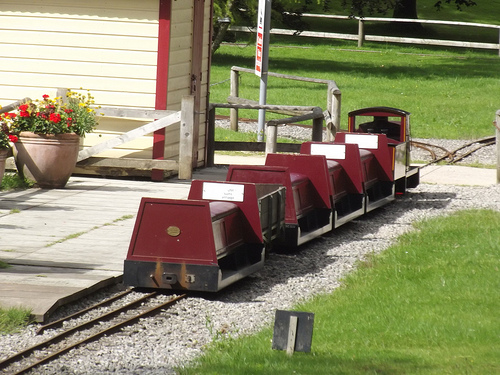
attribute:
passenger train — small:
[120, 104, 421, 295]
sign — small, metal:
[270, 306, 316, 356]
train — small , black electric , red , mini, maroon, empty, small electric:
[119, 102, 421, 293]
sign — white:
[202, 181, 245, 202]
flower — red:
[46, 111, 63, 124]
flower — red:
[6, 134, 19, 143]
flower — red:
[17, 103, 30, 113]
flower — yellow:
[53, 95, 62, 102]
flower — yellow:
[79, 102, 88, 109]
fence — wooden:
[208, 64, 341, 164]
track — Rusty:
[425, 132, 477, 179]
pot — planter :
[14, 128, 81, 185]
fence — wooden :
[312, 10, 469, 53]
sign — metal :
[238, 5, 272, 85]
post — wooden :
[250, 81, 268, 140]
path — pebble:
[134, 301, 228, 354]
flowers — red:
[9, 88, 105, 143]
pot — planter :
[14, 136, 87, 186]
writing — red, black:
[254, 7, 260, 68]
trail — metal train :
[78, 293, 168, 350]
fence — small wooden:
[290, 10, 475, 71]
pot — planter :
[13, 127, 85, 187]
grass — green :
[375, 266, 458, 359]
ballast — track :
[74, 293, 216, 353]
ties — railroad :
[78, 312, 117, 334]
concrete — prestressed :
[26, 276, 50, 304]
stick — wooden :
[84, 119, 184, 151]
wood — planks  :
[117, 110, 179, 138]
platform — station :
[13, 160, 134, 302]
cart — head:
[346, 97, 412, 180]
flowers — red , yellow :
[5, 90, 101, 172]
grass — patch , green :
[371, 230, 472, 364]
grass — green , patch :
[365, 211, 475, 367]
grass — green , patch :
[360, 221, 481, 360]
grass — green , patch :
[404, 226, 484, 363]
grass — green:
[206, 30, 496, 370]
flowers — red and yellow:
[1, 81, 100, 141]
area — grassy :
[385, 0, 392, 3]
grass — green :
[392, 284, 444, 373]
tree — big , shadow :
[227, 34, 480, 78]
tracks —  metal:
[0, 283, 174, 368]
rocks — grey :
[154, 306, 223, 342]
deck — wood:
[0, 107, 321, 327]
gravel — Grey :
[4, 114, 491, 373]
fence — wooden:
[354, 13, 496, 67]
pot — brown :
[4, 120, 90, 200]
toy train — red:
[97, 96, 430, 310]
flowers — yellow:
[60, 85, 100, 138]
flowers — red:
[1, 96, 71, 144]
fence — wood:
[258, 11, 490, 49]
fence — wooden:
[208, 1, 497, 58]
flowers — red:
[1, 93, 78, 143]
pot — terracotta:
[8, 130, 88, 180]